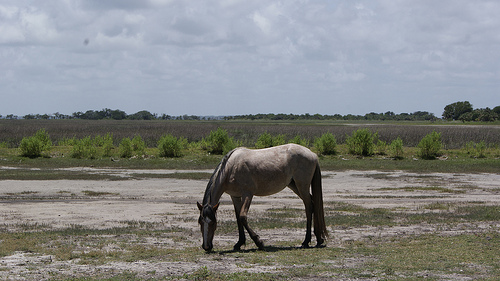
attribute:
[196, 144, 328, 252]
horse — standing, brown, eating, grazing, skinny, pale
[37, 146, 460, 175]
grass — green, sparse, patchy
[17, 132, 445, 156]
bushes — green, many, small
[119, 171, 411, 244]
dirt — brown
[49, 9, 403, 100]
sky — circular, cloudy, overcast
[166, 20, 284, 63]
clouds — white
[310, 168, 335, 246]
tail — long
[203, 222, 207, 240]
markings — white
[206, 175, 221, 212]
neck — bent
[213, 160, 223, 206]
mane — dark